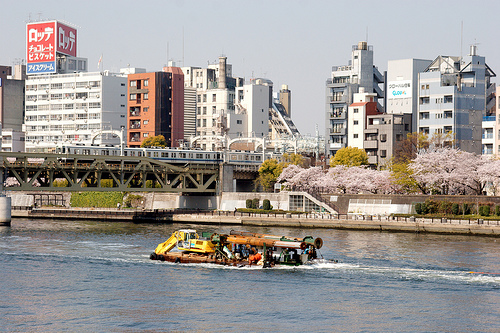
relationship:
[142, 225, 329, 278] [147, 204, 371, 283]
boat in water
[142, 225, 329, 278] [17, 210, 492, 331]
boat in water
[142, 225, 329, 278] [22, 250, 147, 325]
boat moving in water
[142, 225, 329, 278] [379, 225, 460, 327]
boat moving in water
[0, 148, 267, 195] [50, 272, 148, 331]
bridge over water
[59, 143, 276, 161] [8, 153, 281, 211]
train on bridge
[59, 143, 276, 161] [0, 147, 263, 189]
train on bridge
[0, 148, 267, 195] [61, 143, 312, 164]
bridge with train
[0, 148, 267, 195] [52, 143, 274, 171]
bridge with train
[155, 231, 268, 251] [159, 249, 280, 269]
stuff on boat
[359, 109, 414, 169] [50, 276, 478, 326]
building near water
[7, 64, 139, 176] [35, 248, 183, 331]
building near water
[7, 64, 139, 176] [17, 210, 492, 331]
building near water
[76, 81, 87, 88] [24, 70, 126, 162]
window on building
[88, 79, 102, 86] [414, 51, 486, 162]
window on building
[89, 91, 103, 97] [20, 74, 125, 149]
window on building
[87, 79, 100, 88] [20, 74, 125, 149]
window on building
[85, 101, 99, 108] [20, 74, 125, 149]
window on building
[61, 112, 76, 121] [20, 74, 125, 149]
window on building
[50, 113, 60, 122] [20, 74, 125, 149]
window on building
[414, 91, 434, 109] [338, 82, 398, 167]
window on white building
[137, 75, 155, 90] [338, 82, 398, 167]
window on white building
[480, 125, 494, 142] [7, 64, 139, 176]
window on building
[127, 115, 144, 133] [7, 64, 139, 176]
window on building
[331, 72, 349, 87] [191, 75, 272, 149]
window on white building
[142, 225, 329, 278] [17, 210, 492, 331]
boat taking on water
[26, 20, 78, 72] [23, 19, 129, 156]
sign on top of building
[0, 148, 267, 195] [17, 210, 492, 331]
bridge over water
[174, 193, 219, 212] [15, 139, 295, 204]
shadow under bridge